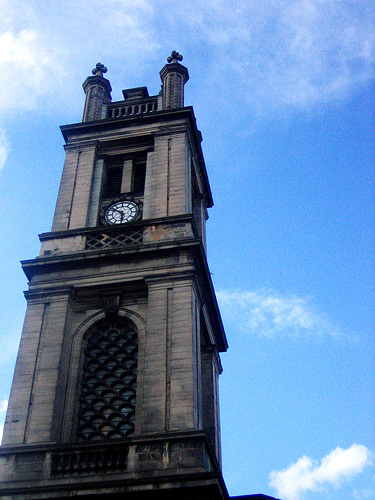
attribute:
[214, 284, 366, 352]
cloud — white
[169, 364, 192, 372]
stone — gray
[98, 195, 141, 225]
clock — white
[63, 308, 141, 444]
window — large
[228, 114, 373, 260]
sky — blue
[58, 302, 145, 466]
window — arch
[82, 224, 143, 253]
hatch pattern — crosshatch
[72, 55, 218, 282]
clock tower — tall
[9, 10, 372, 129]
clouds — white, group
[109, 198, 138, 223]
clock face — clock's, white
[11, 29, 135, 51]
clouds — light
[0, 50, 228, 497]
tower — large, top, clock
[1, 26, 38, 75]
cloud — white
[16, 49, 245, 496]
tower — top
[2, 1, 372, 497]
sky — blue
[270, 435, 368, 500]
clouds — white